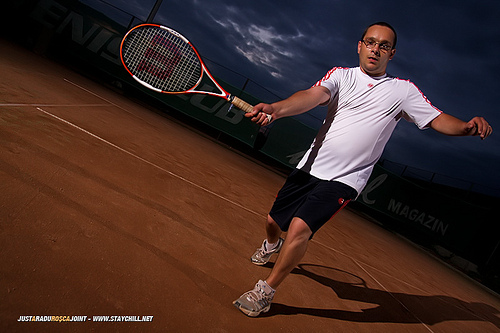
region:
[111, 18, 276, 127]
red and white tennis racket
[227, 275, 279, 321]
grey and white tennis shoe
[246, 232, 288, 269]
grey and white tennis shoe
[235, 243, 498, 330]
shadow of a person holding a racket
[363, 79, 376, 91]
red logo on a white shirt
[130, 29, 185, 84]
red logo on the tennis racket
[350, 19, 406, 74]
head of a person with a racket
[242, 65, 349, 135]
arm of a person with a racket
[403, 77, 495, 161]
arm of a person with a racket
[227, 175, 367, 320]
leg of a person with a racket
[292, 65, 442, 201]
Red and white shirt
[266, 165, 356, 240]
Black and red shorts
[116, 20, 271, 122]
Red and white tennis racket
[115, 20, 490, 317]
Man holding red and white tennis racket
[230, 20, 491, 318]
Man wearing white and red shirt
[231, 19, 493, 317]
Man wearing black and red shorts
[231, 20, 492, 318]
Man wearing glasses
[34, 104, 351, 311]
White line on brown tennis court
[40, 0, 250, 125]
White letters on grenn sign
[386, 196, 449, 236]
White letters on green sign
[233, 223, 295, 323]
two men's shoes on ground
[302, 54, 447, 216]
white and red men's t-shirt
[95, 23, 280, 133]
Wilson tennis racket in hand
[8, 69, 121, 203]
brown tennis court floor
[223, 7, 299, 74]
light clouds in sky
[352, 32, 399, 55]
glasses on guys head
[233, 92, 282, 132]
handle of tennis racket in hand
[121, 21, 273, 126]
the tennis racquet in the man's hand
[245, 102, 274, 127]
the hand holding the racquet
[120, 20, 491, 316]
the man dressed for tennis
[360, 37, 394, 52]
the glasses on the man's face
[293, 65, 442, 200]
the man's white short sleeved shirt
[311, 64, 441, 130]
the red stripes on the sleeves of the shirt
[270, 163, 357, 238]
the dark shorts on the man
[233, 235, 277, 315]
the shoes on the man's feet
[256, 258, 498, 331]
the man's shadow on the ground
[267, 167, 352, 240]
the red parts on the man's black shorts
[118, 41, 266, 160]
A brown handle racket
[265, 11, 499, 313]
a man playing tennis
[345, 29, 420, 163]
A man wearing glasses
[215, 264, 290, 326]
Blue and white sport shoe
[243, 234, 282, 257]
Blue and white sport shoe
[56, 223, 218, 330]
A brown sand tennis court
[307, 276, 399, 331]
A brown sand tennis court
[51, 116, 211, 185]
A brown sand tennis court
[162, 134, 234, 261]
A brown sand tennis court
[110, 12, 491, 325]
man holding a tennis racket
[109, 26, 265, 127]
a white and red racket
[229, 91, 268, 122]
tan handle on racket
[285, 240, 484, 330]
shadow of the man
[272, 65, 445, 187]
man wearing a white shirt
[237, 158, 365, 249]
a pair of black shorts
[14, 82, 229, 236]
lines on the court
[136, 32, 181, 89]
red w on the strings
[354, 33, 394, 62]
a pair of glasses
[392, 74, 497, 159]
man has arm raised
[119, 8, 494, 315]
the man is playing tennis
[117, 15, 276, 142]
the man is holding a racket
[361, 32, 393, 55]
the man is wearing glasses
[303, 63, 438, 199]
the man is wearing a short sleeve shirt